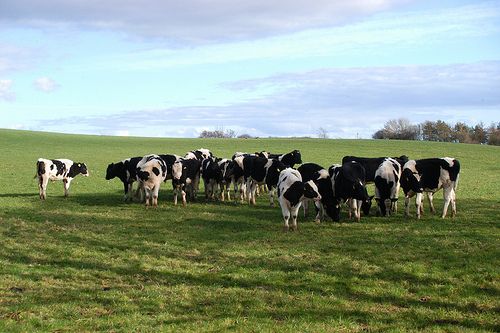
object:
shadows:
[454, 199, 500, 221]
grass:
[1, 126, 497, 330]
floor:
[348, 140, 396, 159]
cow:
[375, 157, 401, 217]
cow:
[34, 155, 89, 199]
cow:
[399, 157, 460, 219]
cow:
[327, 161, 373, 223]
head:
[406, 173, 424, 193]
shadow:
[0, 193, 38, 197]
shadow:
[232, 205, 287, 221]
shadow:
[69, 190, 133, 208]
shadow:
[181, 217, 258, 233]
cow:
[276, 167, 322, 233]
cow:
[105, 156, 143, 201]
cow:
[172, 158, 201, 208]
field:
[0, 126, 500, 333]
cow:
[134, 154, 167, 210]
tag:
[78, 164, 82, 167]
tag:
[366, 200, 369, 203]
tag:
[277, 169, 281, 173]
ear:
[391, 198, 398, 203]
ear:
[375, 198, 381, 201]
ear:
[419, 173, 423, 177]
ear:
[255, 152, 261, 157]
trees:
[470, 121, 491, 144]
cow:
[297, 163, 341, 223]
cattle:
[34, 139, 462, 233]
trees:
[484, 120, 500, 148]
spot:
[413, 173, 421, 181]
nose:
[318, 196, 322, 199]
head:
[361, 195, 375, 215]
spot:
[49, 164, 54, 170]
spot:
[123, 160, 129, 171]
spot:
[152, 167, 160, 177]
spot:
[282, 176, 287, 182]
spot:
[392, 164, 399, 174]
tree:
[224, 129, 238, 138]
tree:
[198, 130, 207, 138]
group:
[196, 126, 236, 138]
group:
[370, 117, 500, 145]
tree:
[385, 118, 410, 140]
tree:
[372, 129, 388, 140]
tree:
[421, 120, 436, 141]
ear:
[78, 162, 82, 168]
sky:
[0, 0, 500, 136]